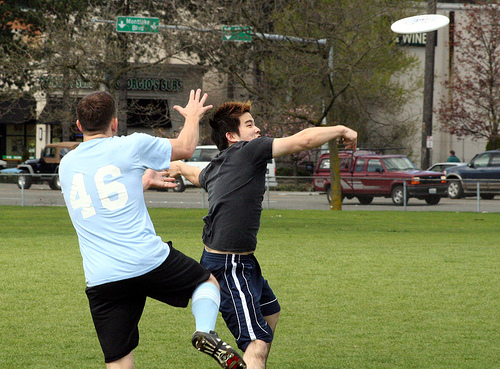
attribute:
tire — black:
[20, 169, 30, 186]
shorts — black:
[77, 236, 216, 365]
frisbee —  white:
[387, 12, 454, 33]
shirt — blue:
[57, 129, 177, 292]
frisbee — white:
[393, 10, 448, 41]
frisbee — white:
[364, 10, 479, 51]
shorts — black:
[85, 245, 217, 360]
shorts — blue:
[186, 231, 324, 350]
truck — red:
[311, 150, 447, 205]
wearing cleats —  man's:
[183, 330, 294, 360]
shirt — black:
[197, 132, 269, 252]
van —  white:
[167, 142, 273, 197]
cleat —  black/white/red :
[188, 331, 244, 367]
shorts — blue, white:
[194, 245, 285, 350]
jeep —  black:
[17, 139, 80, 189]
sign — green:
[107, 16, 164, 40]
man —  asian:
[169, 92, 361, 367]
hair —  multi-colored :
[205, 97, 248, 156]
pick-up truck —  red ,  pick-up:
[311, 149, 450, 205]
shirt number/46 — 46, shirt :
[63, 154, 135, 222]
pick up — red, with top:
[314, 146, 453, 204]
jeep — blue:
[14, 140, 76, 187]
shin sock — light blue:
[188, 277, 228, 337]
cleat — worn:
[188, 329, 248, 367]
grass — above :
[17, 201, 490, 359]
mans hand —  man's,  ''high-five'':
[173, 87, 213, 118]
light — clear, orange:
[423, 171, 463, 195]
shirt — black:
[161, 86, 330, 267]